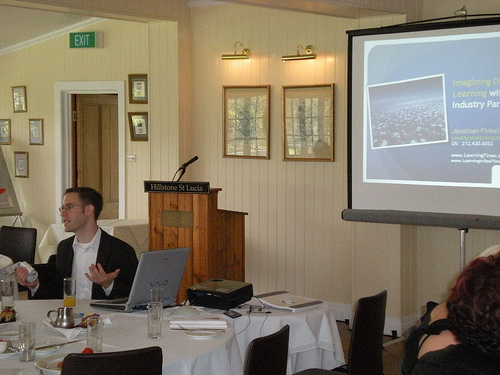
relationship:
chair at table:
[62, 343, 165, 371] [7, 272, 343, 375]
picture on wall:
[222, 87, 277, 167] [185, 11, 407, 342]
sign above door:
[72, 25, 99, 52] [55, 73, 124, 226]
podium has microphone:
[145, 172, 247, 310] [163, 156, 203, 183]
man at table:
[16, 170, 143, 298] [7, 272, 343, 375]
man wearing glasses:
[16, 170, 143, 298] [57, 201, 96, 220]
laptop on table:
[99, 243, 195, 308] [7, 272, 343, 375]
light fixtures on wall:
[212, 41, 327, 69] [185, 11, 407, 342]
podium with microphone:
[145, 172, 247, 310] [163, 156, 203, 183]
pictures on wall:
[6, 77, 52, 190] [4, 23, 149, 258]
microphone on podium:
[163, 156, 203, 183] [145, 172, 247, 310]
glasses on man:
[57, 201, 96, 220] [16, 170, 143, 298]